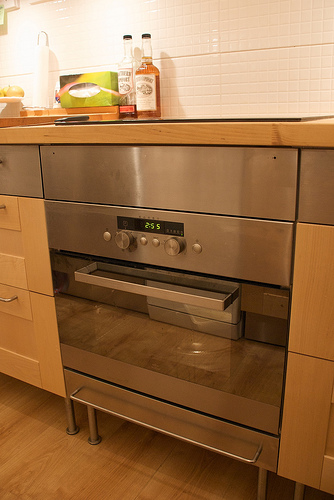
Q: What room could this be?
A: It is a kitchen.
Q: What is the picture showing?
A: It is showing a kitchen.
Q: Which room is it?
A: It is a kitchen.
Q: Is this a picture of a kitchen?
A: Yes, it is showing a kitchen.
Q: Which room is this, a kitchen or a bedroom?
A: It is a kitchen.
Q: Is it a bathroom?
A: No, it is a kitchen.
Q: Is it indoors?
A: Yes, it is indoors.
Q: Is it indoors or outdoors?
A: It is indoors.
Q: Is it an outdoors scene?
A: No, it is indoors.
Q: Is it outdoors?
A: No, it is indoors.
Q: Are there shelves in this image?
A: No, there are no shelves.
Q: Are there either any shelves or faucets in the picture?
A: No, there are no shelves or faucets.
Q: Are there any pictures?
A: No, there are no pictures.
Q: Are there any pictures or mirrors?
A: No, there are no pictures or mirrors.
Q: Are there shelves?
A: No, there are no shelves.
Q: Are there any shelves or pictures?
A: No, there are no shelves or pictures.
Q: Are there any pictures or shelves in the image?
A: No, there are no shelves or pictures.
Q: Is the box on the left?
A: Yes, the box is on the left of the image.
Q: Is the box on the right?
A: No, the box is on the left of the image.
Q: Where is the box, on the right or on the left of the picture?
A: The box is on the left of the image.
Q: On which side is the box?
A: The box is on the left of the image.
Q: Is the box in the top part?
A: Yes, the box is in the top of the image.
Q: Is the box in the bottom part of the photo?
A: No, the box is in the top of the image.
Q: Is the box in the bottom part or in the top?
A: The box is in the top of the image.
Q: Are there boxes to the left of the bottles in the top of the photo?
A: Yes, there is a box to the left of the bottles.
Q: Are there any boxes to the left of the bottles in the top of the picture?
A: Yes, there is a box to the left of the bottles.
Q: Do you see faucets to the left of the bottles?
A: No, there is a box to the left of the bottles.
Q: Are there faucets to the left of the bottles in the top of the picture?
A: No, there is a box to the left of the bottles.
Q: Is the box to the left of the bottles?
A: Yes, the box is to the left of the bottles.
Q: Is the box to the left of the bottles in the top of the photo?
A: Yes, the box is to the left of the bottles.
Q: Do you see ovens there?
A: Yes, there is an oven.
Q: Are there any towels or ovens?
A: Yes, there is an oven.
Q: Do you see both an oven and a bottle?
A: Yes, there are both an oven and a bottle.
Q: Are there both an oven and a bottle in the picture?
A: Yes, there are both an oven and a bottle.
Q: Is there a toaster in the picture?
A: No, there are no toasters.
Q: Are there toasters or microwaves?
A: No, there are no toasters or microwaves.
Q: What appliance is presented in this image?
A: The appliance is an oven.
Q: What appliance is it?
A: The appliance is an oven.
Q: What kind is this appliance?
A: This is an oven.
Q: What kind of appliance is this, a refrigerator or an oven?
A: This is an oven.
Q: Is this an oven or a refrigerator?
A: This is an oven.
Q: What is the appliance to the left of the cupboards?
A: The appliance is an oven.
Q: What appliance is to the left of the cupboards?
A: The appliance is an oven.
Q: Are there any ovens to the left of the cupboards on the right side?
A: Yes, there is an oven to the left of the cupboards.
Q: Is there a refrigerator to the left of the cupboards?
A: No, there is an oven to the left of the cupboards.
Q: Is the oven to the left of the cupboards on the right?
A: Yes, the oven is to the left of the cupboards.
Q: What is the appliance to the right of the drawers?
A: The appliance is an oven.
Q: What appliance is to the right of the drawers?
A: The appliance is an oven.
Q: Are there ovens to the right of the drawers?
A: Yes, there is an oven to the right of the drawers.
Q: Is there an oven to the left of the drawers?
A: No, the oven is to the right of the drawers.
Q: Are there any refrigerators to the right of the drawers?
A: No, there is an oven to the right of the drawers.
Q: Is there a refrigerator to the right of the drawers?
A: No, there is an oven to the right of the drawers.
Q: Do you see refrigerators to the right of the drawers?
A: No, there is an oven to the right of the drawers.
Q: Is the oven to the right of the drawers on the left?
A: Yes, the oven is to the right of the drawers.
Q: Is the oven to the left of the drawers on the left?
A: No, the oven is to the right of the drawers.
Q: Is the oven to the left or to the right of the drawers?
A: The oven is to the right of the drawers.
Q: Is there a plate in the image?
A: No, there are no plates.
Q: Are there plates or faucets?
A: No, there are no plates or faucets.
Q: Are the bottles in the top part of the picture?
A: Yes, the bottles are in the top of the image.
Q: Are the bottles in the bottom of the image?
A: No, the bottles are in the top of the image.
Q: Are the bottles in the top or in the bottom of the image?
A: The bottles are in the top of the image.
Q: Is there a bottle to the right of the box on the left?
A: Yes, there are bottles to the right of the box.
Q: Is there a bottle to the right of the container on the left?
A: Yes, there are bottles to the right of the box.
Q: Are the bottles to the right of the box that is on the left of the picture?
A: Yes, the bottles are to the right of the box.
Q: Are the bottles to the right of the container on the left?
A: Yes, the bottles are to the right of the box.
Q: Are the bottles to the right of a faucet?
A: No, the bottles are to the right of the box.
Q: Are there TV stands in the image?
A: No, there are no TV stands.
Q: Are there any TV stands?
A: No, there are no TV stands.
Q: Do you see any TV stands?
A: No, there are no TV stands.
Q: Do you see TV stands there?
A: No, there are no TV stands.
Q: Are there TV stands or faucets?
A: No, there are no TV stands or faucets.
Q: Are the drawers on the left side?
A: Yes, the drawers are on the left of the image.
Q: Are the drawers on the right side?
A: No, the drawers are on the left of the image.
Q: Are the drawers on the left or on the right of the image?
A: The drawers are on the left of the image.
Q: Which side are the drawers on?
A: The drawers are on the left of the image.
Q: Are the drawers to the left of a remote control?
A: Yes, the drawers are to the left of a remote control.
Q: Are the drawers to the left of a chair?
A: No, the drawers are to the left of a remote control.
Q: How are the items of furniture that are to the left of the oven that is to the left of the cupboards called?
A: The pieces of furniture are drawers.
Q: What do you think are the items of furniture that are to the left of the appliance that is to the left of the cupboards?
A: The pieces of furniture are drawers.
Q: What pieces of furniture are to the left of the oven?
A: The pieces of furniture are drawers.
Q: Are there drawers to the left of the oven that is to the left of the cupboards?
A: Yes, there are drawers to the left of the oven.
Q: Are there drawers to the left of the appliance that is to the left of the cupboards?
A: Yes, there are drawers to the left of the oven.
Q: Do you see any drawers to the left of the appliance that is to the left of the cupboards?
A: Yes, there are drawers to the left of the oven.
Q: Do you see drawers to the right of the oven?
A: No, the drawers are to the left of the oven.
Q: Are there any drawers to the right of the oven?
A: No, the drawers are to the left of the oven.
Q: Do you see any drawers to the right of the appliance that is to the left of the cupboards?
A: No, the drawers are to the left of the oven.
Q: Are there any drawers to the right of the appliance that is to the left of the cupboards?
A: No, the drawers are to the left of the oven.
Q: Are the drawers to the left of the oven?
A: Yes, the drawers are to the left of the oven.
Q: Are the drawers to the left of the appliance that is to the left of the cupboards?
A: Yes, the drawers are to the left of the oven.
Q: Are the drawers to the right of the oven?
A: No, the drawers are to the left of the oven.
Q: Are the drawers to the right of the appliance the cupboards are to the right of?
A: No, the drawers are to the left of the oven.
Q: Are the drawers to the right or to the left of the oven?
A: The drawers are to the left of the oven.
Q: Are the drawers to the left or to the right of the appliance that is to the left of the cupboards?
A: The drawers are to the left of the oven.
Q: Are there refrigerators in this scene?
A: No, there are no refrigerators.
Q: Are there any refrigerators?
A: No, there are no refrigerators.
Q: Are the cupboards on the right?
A: Yes, the cupboards are on the right of the image.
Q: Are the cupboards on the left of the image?
A: No, the cupboards are on the right of the image.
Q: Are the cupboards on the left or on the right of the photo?
A: The cupboards are on the right of the image.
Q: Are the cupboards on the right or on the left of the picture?
A: The cupboards are on the right of the image.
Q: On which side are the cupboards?
A: The cupboards are on the right of the image.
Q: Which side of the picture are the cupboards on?
A: The cupboards are on the right of the image.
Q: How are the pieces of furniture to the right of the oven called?
A: The pieces of furniture are cupboards.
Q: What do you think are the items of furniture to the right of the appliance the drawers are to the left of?
A: The pieces of furniture are cupboards.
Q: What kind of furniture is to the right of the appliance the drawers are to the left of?
A: The pieces of furniture are cupboards.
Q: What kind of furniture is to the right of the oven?
A: The pieces of furniture are cupboards.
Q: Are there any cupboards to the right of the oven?
A: Yes, there are cupboards to the right of the oven.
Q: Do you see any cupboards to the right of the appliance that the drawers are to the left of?
A: Yes, there are cupboards to the right of the oven.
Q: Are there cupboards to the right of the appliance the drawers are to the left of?
A: Yes, there are cupboards to the right of the oven.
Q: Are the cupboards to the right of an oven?
A: Yes, the cupboards are to the right of an oven.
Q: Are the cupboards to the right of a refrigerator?
A: No, the cupboards are to the right of an oven.